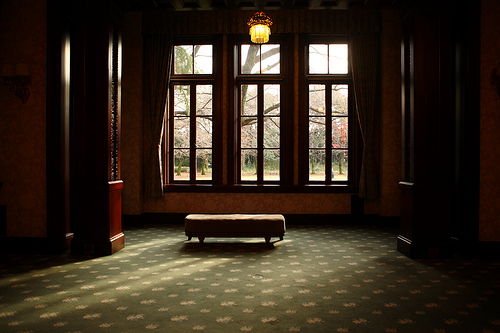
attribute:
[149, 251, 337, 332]
floor — carpet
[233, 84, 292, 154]
window — set, clear, 8 panels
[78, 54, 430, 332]
room — classic, dark, lit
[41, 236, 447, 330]
carpet — green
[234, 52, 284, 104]
glass — window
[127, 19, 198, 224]
curtain — window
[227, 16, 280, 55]
light — ceiling, dim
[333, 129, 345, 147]
flower — red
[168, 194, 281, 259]
sofa — brown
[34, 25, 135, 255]
pole — wood